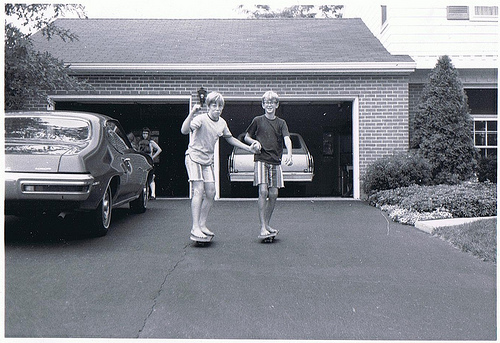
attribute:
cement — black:
[5, 192, 498, 341]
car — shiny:
[10, 111, 167, 243]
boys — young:
[181, 89, 291, 241]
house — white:
[7, 19, 498, 193]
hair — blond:
[206, 88, 223, 109]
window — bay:
[470, 117, 498, 146]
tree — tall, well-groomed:
[409, 47, 482, 189]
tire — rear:
[82, 181, 114, 240]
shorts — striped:
[180, 149, 219, 191]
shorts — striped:
[244, 156, 286, 196]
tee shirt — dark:
[240, 108, 295, 169]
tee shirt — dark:
[178, 108, 238, 168]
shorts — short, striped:
[184, 153, 216, 183]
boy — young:
[242, 85, 294, 235]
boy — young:
[178, 87, 259, 239]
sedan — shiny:
[6, 112, 155, 237]